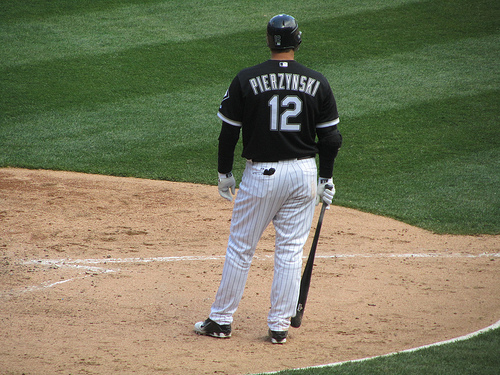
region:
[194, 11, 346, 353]
baseball player Pierzynski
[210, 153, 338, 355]
white pants with thin black stripes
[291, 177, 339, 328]
black baseball bat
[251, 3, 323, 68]
black baseball helmet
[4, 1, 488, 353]
baseball player standing on the infield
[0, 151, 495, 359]
baseball infield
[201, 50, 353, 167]
black and white teeshirt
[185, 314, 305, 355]
black and white shoes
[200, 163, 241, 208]
White left-handed men's glove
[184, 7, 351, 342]
man holding a baseball bat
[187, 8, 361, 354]
a baseball player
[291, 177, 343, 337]
a black bat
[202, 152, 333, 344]
the pants are white with black stripes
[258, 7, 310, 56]
man wearing a black helmet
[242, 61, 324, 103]
white letters on the players back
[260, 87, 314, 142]
the numbers 1 and 2 are on the uniform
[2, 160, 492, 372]
the player is standing on dirt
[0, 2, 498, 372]
the grass is green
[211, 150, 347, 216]
a player wearing gloves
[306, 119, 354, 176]
player wearing elbow protection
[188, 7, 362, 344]
jersey shown is black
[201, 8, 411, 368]
jersey has white letters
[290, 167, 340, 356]
bat is black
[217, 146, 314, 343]
baseball pants with pinstripes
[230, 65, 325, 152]
jersey with number 12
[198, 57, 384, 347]
baseball player standing waiting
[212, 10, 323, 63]
batters helmet is black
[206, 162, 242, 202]
batters gloves are white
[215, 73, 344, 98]
Pierzynski on back of jersey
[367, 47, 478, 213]
green grass with stripes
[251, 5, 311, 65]
This is a helmet.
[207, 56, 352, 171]
This is a shirt.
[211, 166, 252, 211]
This is the left hand.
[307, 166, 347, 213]
This is the right hand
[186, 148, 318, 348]
This is a pair of pants.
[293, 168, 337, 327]
This is a bat.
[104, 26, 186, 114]
This is green grass.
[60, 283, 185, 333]
This is brown dirt.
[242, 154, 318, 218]
This is a butt.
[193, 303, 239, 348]
This is a left hand.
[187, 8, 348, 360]
Baseball player wearing a uniform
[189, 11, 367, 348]
Baseball player holding a baseball bat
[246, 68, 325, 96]
Baseball player's last name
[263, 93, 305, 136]
Baseball player's number on the back of his jersey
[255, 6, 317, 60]
Batter's safety helmet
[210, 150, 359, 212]
Man wearing white gloves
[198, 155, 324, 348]
Man's white striped pants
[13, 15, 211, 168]
Green grass on the baseball field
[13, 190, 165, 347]
Dirt ground where the players run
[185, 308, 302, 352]
Man's baseball cleats